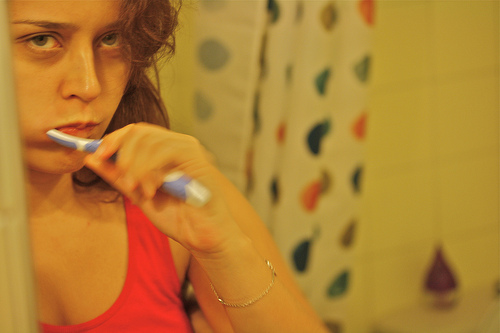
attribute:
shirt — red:
[36, 193, 192, 331]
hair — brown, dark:
[70, 0, 185, 203]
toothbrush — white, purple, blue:
[45, 127, 211, 207]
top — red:
[36, 194, 193, 331]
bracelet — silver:
[207, 257, 278, 308]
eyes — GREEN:
[13, 20, 121, 55]